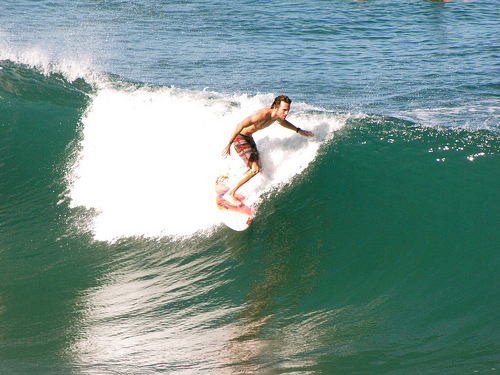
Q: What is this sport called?
A: Surfing.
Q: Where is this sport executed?
A: Ocean.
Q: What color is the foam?
A: White.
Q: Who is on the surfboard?
A: A man.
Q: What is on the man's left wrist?
A: Watch.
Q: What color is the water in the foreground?
A: Green.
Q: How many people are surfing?
A: 1.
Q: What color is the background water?
A: Blue.